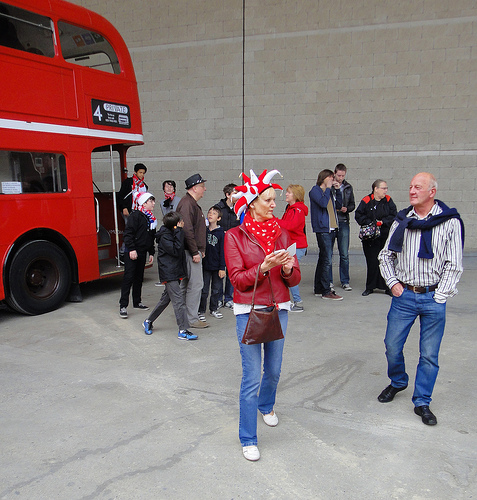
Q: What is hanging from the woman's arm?
A: Purse.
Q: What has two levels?
A: Bus.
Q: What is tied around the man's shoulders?
A: Sweater.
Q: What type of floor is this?
A: Concrete.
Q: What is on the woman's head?
A: Jester hat.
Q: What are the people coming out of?
A: Bus.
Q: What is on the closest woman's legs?
A: Jeans.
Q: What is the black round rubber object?
A: Tire.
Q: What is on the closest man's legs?
A: Jeans.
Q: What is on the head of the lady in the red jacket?
A: A jester hat.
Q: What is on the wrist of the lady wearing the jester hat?
A: A purse.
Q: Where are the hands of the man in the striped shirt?
A: In his pockets.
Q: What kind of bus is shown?
A: A red double decker.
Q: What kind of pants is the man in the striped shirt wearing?
A: Blue jeans.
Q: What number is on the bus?
A: Four.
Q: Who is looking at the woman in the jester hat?
A: The man in the striped shirt.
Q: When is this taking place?
A: Daytime.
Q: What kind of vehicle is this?
A: Bus.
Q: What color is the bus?
A: Red.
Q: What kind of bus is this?
A: Double decker.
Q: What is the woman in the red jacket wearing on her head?
A: Hat.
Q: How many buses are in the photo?
A: One.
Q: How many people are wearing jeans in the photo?
A: Four.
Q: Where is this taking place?
A: At a bus station.